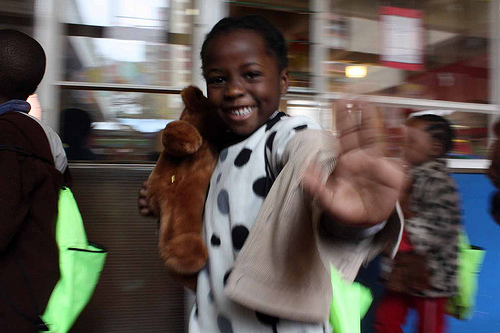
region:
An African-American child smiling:
[189, 10, 298, 142]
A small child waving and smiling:
[157, 10, 442, 285]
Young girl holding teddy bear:
[152, 13, 289, 276]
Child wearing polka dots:
[145, 14, 370, 319]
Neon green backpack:
[36, 173, 123, 325]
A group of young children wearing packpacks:
[6, 25, 494, 325]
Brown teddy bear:
[130, 83, 226, 277]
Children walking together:
[124, 21, 484, 325]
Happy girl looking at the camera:
[195, 7, 409, 329]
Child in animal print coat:
[380, 92, 475, 296]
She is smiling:
[169, 20, 314, 143]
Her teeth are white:
[219, 102, 274, 125]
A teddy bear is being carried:
[113, 70, 233, 298]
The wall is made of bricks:
[93, 196, 155, 303]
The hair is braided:
[383, 95, 464, 183]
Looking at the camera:
[191, 52, 272, 92]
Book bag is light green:
[23, 163, 133, 331]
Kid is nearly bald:
[5, 24, 62, 126]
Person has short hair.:
[207, 9, 296, 54]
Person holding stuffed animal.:
[153, 100, 203, 189]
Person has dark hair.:
[4, 43, 46, 81]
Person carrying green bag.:
[48, 213, 106, 284]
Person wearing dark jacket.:
[14, 152, 64, 233]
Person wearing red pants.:
[385, 295, 440, 321]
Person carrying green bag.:
[442, 232, 490, 289]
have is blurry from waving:
[283, 93, 425, 223]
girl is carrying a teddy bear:
[117, 94, 217, 275]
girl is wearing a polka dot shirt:
[196, 115, 310, 328]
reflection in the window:
[52, 0, 176, 146]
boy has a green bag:
[46, 145, 132, 331]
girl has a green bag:
[446, 195, 484, 321]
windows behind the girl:
[286, 0, 499, 109]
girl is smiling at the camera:
[194, 6, 294, 141]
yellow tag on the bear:
[162, 168, 177, 187]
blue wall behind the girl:
[461, 178, 497, 310]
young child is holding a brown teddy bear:
[142, 7, 416, 332]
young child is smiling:
[136, 16, 420, 324]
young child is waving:
[127, 13, 424, 327]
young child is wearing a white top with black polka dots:
[141, 12, 407, 329]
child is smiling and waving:
[138, 11, 413, 331]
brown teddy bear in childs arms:
[148, 79, 227, 275]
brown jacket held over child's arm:
[216, 123, 366, 323]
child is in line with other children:
[4, 24, 479, 329]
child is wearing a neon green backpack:
[2, 26, 115, 330]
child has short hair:
[145, 16, 405, 330]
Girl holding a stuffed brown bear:
[137, 8, 422, 332]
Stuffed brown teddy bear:
[143, 80, 228, 275]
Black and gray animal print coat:
[400, 155, 475, 300]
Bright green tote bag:
[39, 180, 111, 332]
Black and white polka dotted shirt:
[183, 107, 358, 332]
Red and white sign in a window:
[379, 3, 434, 75]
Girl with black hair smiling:
[189, 10, 295, 137]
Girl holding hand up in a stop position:
[135, 11, 420, 331]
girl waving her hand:
[149, 15, 406, 332]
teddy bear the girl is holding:
[150, 80, 230, 275]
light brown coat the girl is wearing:
[218, 120, 406, 321]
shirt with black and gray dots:
[186, 114, 337, 332]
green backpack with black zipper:
[32, 177, 115, 332]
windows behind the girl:
[2, 2, 499, 158]